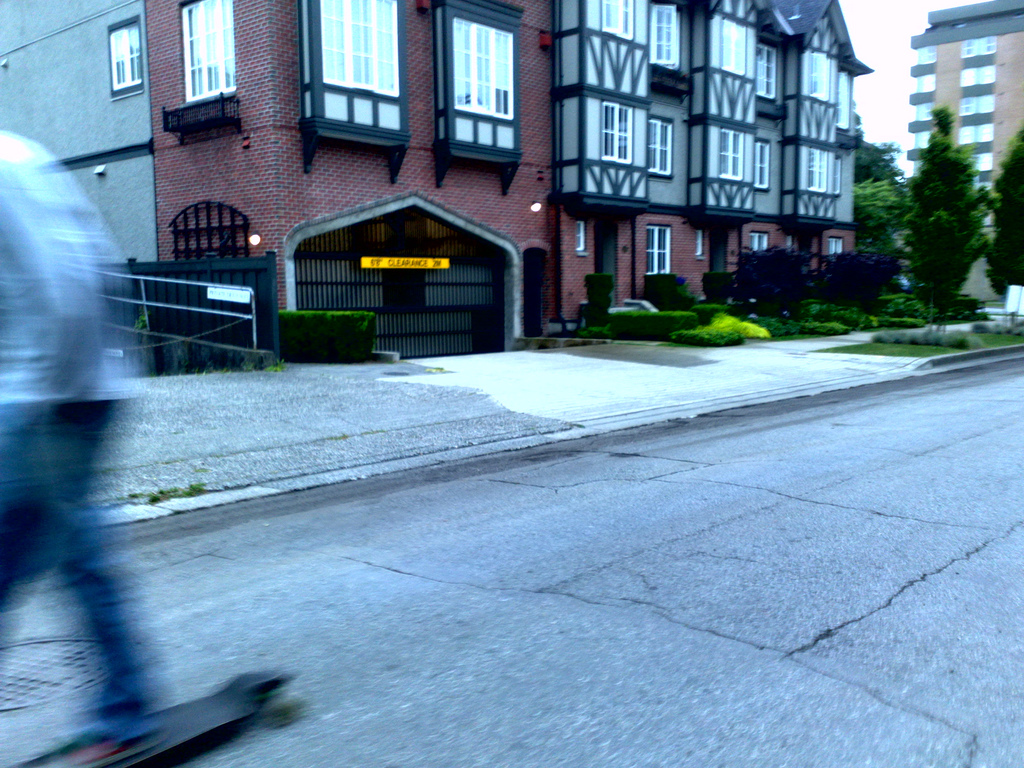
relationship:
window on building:
[649, 226, 675, 277] [1, 1, 869, 352]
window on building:
[690, 232, 703, 256] [1, 1, 869, 352]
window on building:
[576, 226, 586, 255] [1, 1, 869, 352]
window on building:
[109, 21, 139, 97] [1, 1, 869, 352]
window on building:
[602, 102, 631, 163] [1, 1, 869, 352]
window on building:
[636, 112, 695, 180] [1, 1, 869, 352]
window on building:
[717, 119, 736, 177] [1, 1, 869, 352]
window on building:
[748, 143, 774, 194] [1, 1, 869, 352]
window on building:
[783, 147, 831, 199] [1, 1, 869, 352]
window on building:
[695, 230, 703, 256] [1, 1, 869, 352]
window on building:
[745, 207, 769, 252] [1, 1, 869, 352]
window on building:
[794, 224, 858, 260] [1, 1, 869, 352]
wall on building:
[257, 23, 572, 233] [1, 1, 869, 352]